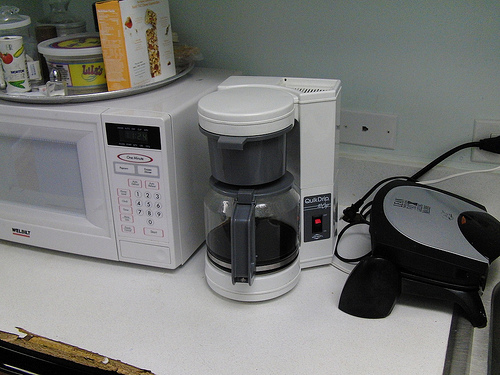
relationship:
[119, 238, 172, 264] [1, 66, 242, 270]
button on front of microwave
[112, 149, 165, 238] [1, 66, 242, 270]
buttons on front of microwave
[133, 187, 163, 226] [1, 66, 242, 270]
number pad on front of microwave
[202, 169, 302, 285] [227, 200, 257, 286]
coffee pot has handle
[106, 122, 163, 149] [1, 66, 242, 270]
display on front of microwave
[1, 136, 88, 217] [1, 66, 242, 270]
window on front of microwave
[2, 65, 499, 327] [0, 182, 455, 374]
appliances on top of counter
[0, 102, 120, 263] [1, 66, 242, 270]
door on front of microwave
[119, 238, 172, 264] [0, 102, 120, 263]
button to open door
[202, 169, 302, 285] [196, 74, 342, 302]
coffee pot on coffee maker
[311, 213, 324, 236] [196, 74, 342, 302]
switch on side of coffee maker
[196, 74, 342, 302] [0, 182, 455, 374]
coffee maker on top of counter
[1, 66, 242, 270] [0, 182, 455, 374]
microwave on top of counter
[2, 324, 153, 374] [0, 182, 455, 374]
crack on top of counter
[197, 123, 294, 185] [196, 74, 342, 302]
filter basket part of coffee maker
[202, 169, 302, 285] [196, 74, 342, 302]
coffee pot inside coffee maker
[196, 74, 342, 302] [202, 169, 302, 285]
coffee maker with coffee pot